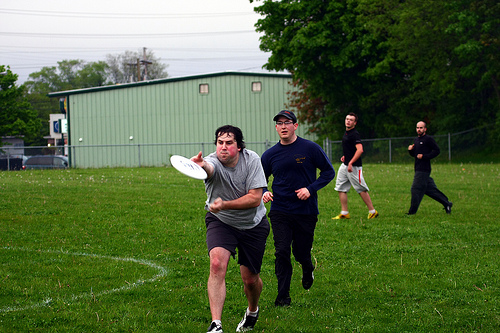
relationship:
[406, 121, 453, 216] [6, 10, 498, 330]
guys on photo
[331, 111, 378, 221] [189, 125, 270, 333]
man on guy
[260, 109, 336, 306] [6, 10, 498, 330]
man on photo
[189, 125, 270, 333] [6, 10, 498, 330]
guy on photo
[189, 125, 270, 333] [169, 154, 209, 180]
guy playing frisbee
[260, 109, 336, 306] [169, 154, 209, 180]
man playing frisbee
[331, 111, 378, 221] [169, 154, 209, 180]
man playing frisbee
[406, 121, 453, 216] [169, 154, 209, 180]
guys playing frisbee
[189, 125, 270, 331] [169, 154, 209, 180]
guy throwing frisbee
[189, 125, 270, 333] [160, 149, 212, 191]
guy waiting for frisbee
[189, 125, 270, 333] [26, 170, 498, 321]
guy on field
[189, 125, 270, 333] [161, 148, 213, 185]
guy throwing frisbee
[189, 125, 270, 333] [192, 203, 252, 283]
guy wears pants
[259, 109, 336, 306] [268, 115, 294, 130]
man wears glasses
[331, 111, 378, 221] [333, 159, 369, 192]
man wears shorts